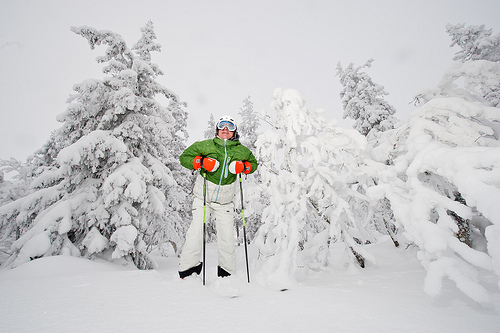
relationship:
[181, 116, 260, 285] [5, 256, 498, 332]
man standing on snow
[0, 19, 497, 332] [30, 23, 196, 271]
snow covering tree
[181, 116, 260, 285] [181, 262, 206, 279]
man wearing shoe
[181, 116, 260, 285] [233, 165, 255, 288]
man holding ski pole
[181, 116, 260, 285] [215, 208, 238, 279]
man has leg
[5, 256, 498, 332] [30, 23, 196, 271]
snow under tree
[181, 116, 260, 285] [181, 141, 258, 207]
man wearing jacket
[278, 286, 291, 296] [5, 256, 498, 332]
ski covered with snow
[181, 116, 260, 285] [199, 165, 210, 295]
man holding ski pole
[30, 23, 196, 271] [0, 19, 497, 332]
tree covered in snow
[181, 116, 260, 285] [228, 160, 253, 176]
man wearing glove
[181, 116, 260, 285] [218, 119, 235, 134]
man wearing goggles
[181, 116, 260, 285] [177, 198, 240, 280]
man wearing pants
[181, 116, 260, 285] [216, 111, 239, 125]
man wearing helmet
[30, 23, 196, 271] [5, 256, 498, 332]
tree covered snow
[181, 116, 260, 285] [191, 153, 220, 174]
man wearing glove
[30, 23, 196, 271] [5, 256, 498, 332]
tree covered in snow